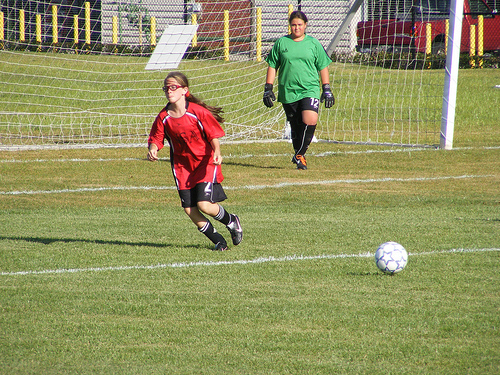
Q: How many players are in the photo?
A: Two.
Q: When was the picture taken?
A: Daytime.